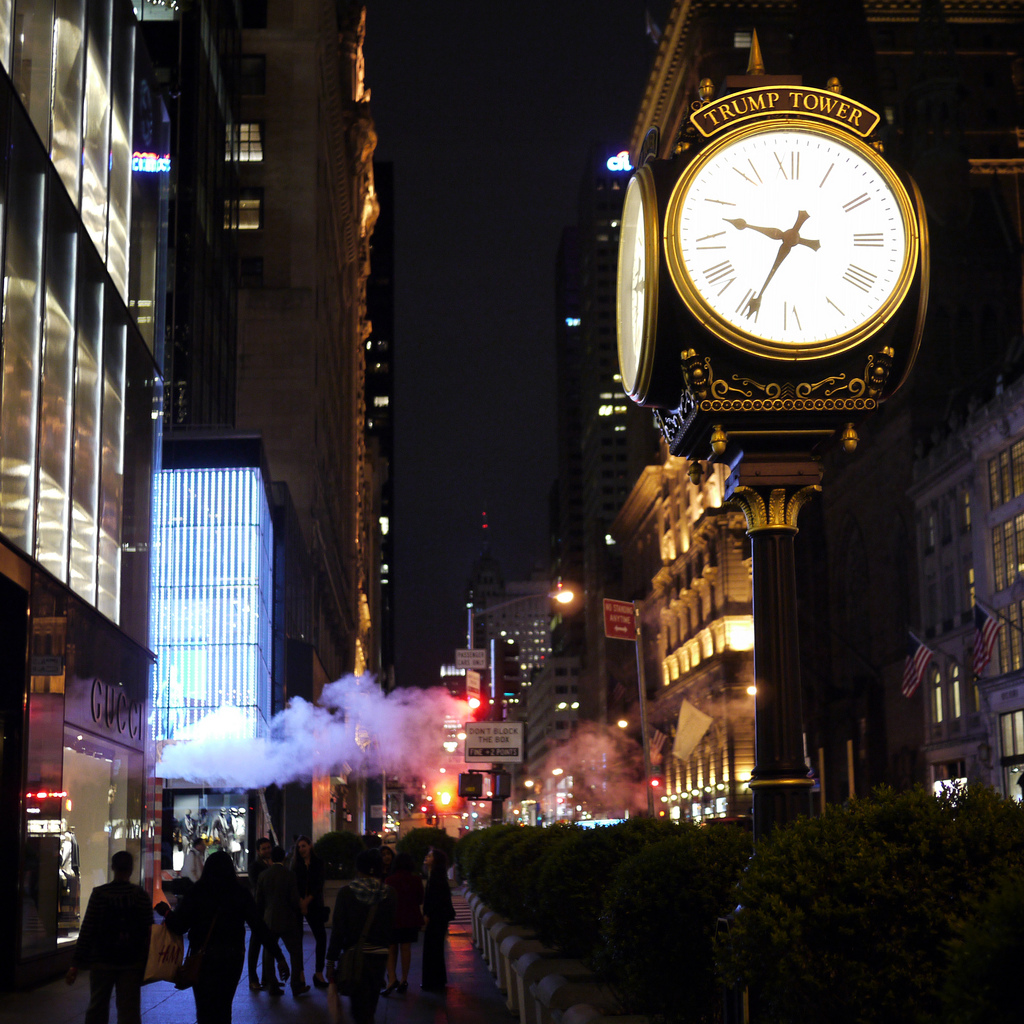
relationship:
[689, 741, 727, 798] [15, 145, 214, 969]
window on building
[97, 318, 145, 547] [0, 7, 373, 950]
window on building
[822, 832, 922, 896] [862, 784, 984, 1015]
leaves on bush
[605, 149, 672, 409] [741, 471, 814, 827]
clock on pole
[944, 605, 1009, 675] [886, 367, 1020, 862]
american flag on building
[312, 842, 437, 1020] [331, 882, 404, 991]
woman carrying backpack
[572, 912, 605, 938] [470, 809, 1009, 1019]
leaves on bush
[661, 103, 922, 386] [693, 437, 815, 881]
clock on pole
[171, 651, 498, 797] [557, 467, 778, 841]
steam from building